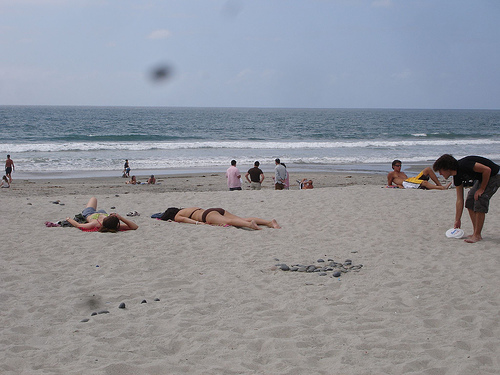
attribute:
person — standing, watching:
[247, 159, 266, 192]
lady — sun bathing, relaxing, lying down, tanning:
[155, 204, 282, 233]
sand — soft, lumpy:
[2, 163, 498, 374]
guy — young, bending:
[434, 151, 500, 245]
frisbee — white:
[444, 226, 467, 241]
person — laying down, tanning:
[63, 193, 140, 236]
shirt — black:
[452, 154, 499, 187]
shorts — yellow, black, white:
[407, 168, 429, 188]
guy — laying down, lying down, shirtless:
[385, 159, 453, 192]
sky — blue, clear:
[1, 0, 499, 108]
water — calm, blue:
[0, 107, 499, 179]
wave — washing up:
[4, 155, 500, 171]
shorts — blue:
[81, 206, 107, 216]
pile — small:
[272, 254, 364, 280]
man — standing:
[5, 153, 17, 184]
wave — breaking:
[0, 132, 499, 155]